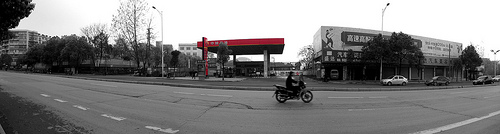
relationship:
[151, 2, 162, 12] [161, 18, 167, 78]
street light supported on pole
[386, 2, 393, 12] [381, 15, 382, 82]
street light supported on pole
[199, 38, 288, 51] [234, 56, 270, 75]
canopy over building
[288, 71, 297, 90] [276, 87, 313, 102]
person riding on motorcycle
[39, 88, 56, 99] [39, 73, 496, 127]
line painted on street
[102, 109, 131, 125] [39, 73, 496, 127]
line painted on street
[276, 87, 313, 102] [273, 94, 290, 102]
motorcycle has wheel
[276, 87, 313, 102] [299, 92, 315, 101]
motorcycle has wheel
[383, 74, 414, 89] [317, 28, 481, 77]
car next to building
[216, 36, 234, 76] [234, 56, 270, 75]
tree next to building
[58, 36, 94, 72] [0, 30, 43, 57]
tree next to building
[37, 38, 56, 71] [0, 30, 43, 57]
tree next to building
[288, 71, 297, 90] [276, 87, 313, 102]
person driving motorcycle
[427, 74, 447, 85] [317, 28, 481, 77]
car parked next to building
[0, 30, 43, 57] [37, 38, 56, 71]
building behind tree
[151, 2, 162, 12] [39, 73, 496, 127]
street light hanging over street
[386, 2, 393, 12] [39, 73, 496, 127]
street light over street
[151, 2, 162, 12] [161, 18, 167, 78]
street light hanging on pole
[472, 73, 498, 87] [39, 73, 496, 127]
car parked on street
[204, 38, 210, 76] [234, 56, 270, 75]
sign in front of building